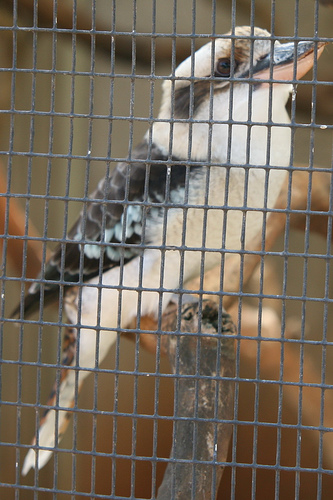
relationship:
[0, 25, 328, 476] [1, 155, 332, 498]
bird on wooden perch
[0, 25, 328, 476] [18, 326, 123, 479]
bird has tail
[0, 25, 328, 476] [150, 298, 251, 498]
bird on perch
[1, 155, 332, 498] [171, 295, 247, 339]
wooden perch has knot area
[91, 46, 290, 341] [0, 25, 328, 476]
feathers on bird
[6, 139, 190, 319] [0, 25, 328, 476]
wing on bird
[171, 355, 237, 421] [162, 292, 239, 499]
part of branch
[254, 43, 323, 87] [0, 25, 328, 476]
beak of bird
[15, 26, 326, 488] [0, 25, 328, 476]
feathers of bird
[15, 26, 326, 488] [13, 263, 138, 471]
feathers of tail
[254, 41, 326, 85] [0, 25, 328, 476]
beak on bird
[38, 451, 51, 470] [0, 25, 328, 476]
tail of bird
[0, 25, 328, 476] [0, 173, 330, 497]
bird on branch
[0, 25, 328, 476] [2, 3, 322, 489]
bird in cage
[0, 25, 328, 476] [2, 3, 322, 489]
bird looking up in cage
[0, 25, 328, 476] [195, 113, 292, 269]
bird on belly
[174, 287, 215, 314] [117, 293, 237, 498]
claws wrapped around branch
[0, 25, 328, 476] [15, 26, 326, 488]
bird with feathers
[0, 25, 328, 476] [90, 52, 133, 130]
bird behind wire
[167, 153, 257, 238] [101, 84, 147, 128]
bird behind wire